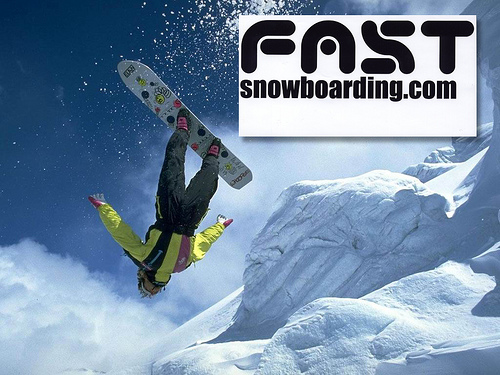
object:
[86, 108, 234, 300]
snowboarder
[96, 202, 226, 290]
coat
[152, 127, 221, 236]
pants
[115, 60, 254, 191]
snowboard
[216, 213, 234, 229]
gloves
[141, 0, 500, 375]
mountains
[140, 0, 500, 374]
snow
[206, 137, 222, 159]
boots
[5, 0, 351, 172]
snow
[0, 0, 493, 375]
air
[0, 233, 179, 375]
clouds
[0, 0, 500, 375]
sky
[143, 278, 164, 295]
goggles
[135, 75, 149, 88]
stickers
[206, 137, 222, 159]
feet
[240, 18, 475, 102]
logo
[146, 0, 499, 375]
ice